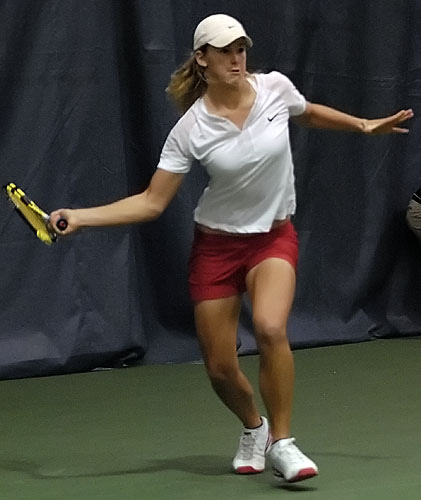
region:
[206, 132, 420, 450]
a woman playing tennis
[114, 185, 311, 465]
a woman playing tennis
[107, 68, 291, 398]
a woman playing tennis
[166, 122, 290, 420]
a woman in white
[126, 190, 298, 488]
a woman in white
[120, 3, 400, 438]
a woman in white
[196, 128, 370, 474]
a woman in white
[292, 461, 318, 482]
Front of the shoe is red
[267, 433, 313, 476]
Most of the shoe is white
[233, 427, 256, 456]
The shoe has white laces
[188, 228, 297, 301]
The shorts are red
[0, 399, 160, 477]
The ground is green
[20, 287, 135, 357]
The backdrop is blue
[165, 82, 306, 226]
The shirt is white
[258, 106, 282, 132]
A black Nike logo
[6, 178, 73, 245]
The tennis racquet is black and yellow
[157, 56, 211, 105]
The hair is blonde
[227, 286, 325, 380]
left knee of player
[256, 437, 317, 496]
left shoe of player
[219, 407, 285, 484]
right shoe of player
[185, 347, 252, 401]
right knee of player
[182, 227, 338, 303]
red shorts of player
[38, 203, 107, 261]
right hand of player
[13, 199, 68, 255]
black and yellow racquet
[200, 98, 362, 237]
white nike shirt on player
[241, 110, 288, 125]
black nike logo on shirt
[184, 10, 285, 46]
white nike hat on player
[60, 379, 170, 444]
the green tennis court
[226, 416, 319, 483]
the shoes on the woman's feet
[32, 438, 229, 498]
the woman's shadow on the ground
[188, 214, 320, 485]
the woman's legs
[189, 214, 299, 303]
the woman's red shorts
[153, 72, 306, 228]
the woman's white shirt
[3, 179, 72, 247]
the yellow and black tennis racquet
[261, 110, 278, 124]
the nike logo on the shirt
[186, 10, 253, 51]
the light colored hat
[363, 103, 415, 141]
the left hand